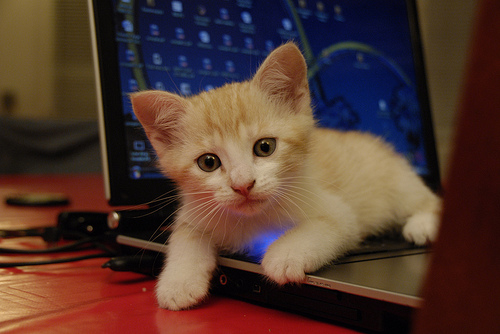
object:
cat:
[123, 37, 446, 310]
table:
[0, 170, 361, 333]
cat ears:
[256, 40, 308, 112]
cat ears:
[128, 90, 190, 146]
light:
[245, 230, 285, 260]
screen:
[110, 0, 442, 182]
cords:
[0, 253, 108, 268]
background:
[4, 2, 500, 190]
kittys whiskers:
[187, 188, 211, 197]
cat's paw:
[257, 243, 324, 280]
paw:
[156, 261, 211, 311]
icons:
[152, 53, 163, 65]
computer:
[75, 0, 435, 320]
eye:
[248, 138, 278, 159]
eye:
[188, 151, 224, 172]